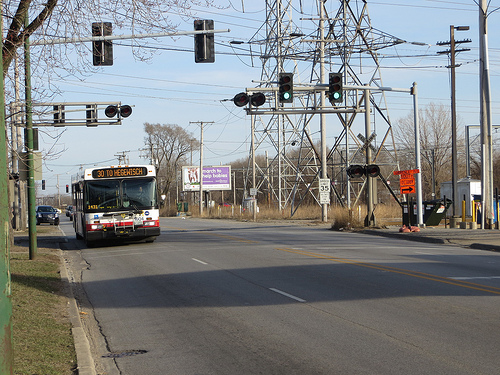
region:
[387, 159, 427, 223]
bright orange detour sign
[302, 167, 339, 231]
speed limit sign on a post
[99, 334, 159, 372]
man hole cover in the street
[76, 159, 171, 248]
public transportation bus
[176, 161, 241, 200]
billboard with a purple background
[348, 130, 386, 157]
railroad crossing sign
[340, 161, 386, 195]
lights on a railroad crossing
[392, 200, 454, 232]
dumpster in a parking lot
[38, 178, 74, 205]
stop lights in the distance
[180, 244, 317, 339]
white dashed line on roadway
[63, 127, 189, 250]
A bus is visible.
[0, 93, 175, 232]
A bus is visible.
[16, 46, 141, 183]
A bus is visible.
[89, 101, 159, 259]
A bus is visible.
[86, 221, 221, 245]
Front stripe on bus.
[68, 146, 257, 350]
Bus is mostly white.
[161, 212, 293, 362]
White lines in road.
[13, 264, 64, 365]
Grassy area near curb.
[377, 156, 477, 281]
Orange signs with black writing.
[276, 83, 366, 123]
Traffic lights are light up green.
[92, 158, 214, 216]
Orange writing on bus.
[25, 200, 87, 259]
Black vehicle behind bus.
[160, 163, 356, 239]
Purple and white sign in background.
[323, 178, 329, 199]
Speed limit is 35.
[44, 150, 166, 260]
a bus driving down the street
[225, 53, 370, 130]
the traffic light is green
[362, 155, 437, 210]
the sign is orange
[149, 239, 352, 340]
the lines on the street are white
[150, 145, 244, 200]
a billboard in the background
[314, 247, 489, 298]
yellow double lines in the street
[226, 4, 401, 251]
a tower of metal bars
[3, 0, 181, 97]
a bare tree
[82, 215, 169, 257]
the bus has headlights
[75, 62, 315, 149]
the sky is partly cloudy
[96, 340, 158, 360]
manhole cover on the street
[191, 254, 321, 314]
white dashed lines on the road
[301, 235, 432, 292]
double yellow line on the road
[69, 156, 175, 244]
large white public bus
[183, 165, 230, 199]
purple bill board at side of road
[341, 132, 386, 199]
rail road crossing sign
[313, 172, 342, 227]
white speed limit sign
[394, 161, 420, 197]
orange detour sign on post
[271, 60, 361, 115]
street lights shining green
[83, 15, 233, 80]
back side of two street lights on a pole